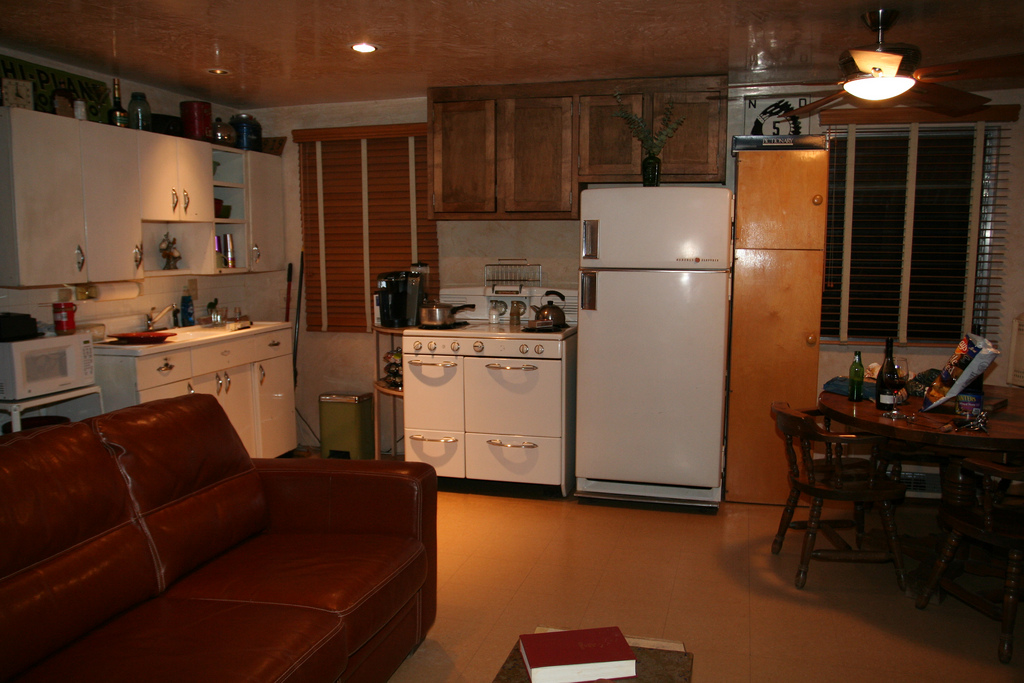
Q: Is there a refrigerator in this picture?
A: Yes, there is a refrigerator.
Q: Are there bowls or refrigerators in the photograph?
A: Yes, there is a refrigerator.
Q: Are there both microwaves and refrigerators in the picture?
A: Yes, there are both a refrigerator and a microwave.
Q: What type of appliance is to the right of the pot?
A: The appliance is a refrigerator.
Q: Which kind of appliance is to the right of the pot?
A: The appliance is a refrigerator.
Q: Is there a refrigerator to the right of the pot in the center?
A: Yes, there is a refrigerator to the right of the pot.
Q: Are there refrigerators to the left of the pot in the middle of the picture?
A: No, the refrigerator is to the right of the pot.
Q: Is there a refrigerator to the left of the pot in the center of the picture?
A: No, the refrigerator is to the right of the pot.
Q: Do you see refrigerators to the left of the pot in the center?
A: No, the refrigerator is to the right of the pot.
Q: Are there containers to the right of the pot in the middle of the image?
A: No, there is a refrigerator to the right of the pot.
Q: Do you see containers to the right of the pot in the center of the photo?
A: No, there is a refrigerator to the right of the pot.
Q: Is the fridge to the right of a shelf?
A: No, the fridge is to the right of the pot.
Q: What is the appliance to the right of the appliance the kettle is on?
A: The appliance is a refrigerator.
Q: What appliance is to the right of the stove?
A: The appliance is a refrigerator.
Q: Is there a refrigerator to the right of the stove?
A: Yes, there is a refrigerator to the right of the stove.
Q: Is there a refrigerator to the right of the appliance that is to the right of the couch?
A: Yes, there is a refrigerator to the right of the stove.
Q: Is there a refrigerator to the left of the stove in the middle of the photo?
A: No, the refrigerator is to the right of the stove.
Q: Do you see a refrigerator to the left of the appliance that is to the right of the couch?
A: No, the refrigerator is to the right of the stove.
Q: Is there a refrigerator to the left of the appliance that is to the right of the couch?
A: No, the refrigerator is to the right of the stove.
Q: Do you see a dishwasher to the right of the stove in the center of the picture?
A: No, there is a refrigerator to the right of the stove.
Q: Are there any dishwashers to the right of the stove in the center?
A: No, there is a refrigerator to the right of the stove.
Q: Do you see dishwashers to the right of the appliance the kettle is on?
A: No, there is a refrigerator to the right of the stove.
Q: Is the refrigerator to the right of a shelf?
A: No, the refrigerator is to the right of the stove.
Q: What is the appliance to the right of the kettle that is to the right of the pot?
A: The appliance is a refrigerator.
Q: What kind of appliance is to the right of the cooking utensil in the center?
A: The appliance is a refrigerator.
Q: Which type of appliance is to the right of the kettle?
A: The appliance is a refrigerator.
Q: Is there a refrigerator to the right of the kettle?
A: Yes, there is a refrigerator to the right of the kettle.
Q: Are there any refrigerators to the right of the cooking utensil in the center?
A: Yes, there is a refrigerator to the right of the kettle.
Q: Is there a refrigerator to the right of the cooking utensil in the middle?
A: Yes, there is a refrigerator to the right of the kettle.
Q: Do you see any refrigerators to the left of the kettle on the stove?
A: No, the refrigerator is to the right of the kettle.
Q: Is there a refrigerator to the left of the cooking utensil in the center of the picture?
A: No, the refrigerator is to the right of the kettle.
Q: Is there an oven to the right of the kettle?
A: No, there is a refrigerator to the right of the kettle.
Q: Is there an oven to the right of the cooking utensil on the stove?
A: No, there is a refrigerator to the right of the kettle.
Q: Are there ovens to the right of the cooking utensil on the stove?
A: No, there is a refrigerator to the right of the kettle.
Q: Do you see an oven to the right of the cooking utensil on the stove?
A: No, there is a refrigerator to the right of the kettle.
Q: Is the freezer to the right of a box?
A: No, the freezer is to the right of a kettle.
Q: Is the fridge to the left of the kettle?
A: No, the fridge is to the right of the kettle.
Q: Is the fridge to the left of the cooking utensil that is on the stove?
A: No, the fridge is to the right of the kettle.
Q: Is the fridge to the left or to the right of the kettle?
A: The fridge is to the right of the kettle.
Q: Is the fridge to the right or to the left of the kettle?
A: The fridge is to the right of the kettle.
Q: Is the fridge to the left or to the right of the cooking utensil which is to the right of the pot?
A: The fridge is to the right of the kettle.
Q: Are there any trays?
A: No, there are no trays.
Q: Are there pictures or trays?
A: No, there are no trays or pictures.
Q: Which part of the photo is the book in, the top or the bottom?
A: The book is in the bottom of the image.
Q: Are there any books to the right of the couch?
A: Yes, there is a book to the right of the couch.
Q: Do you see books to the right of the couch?
A: Yes, there is a book to the right of the couch.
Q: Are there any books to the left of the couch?
A: No, the book is to the right of the couch.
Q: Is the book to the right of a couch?
A: Yes, the book is to the right of a couch.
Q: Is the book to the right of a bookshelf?
A: No, the book is to the right of a couch.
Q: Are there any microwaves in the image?
A: Yes, there is a microwave.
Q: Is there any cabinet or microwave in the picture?
A: Yes, there is a microwave.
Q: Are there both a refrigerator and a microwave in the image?
A: Yes, there are both a microwave and a refrigerator.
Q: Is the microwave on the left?
A: Yes, the microwave is on the left of the image.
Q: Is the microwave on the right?
A: No, the microwave is on the left of the image.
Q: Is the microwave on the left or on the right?
A: The microwave is on the left of the image.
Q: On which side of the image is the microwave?
A: The microwave is on the left of the image.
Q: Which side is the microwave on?
A: The microwave is on the left of the image.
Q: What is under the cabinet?
A: The microwave is under the cabinet.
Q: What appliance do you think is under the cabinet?
A: The appliance is a microwave.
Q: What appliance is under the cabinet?
A: The appliance is a microwave.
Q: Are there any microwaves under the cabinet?
A: Yes, there is a microwave under the cabinet.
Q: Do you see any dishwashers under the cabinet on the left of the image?
A: No, there is a microwave under the cabinet.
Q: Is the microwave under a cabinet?
A: Yes, the microwave is under a cabinet.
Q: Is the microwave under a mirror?
A: No, the microwave is under a cabinet.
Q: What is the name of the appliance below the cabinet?
A: The appliance is a microwave.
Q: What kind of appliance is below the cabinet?
A: The appliance is a microwave.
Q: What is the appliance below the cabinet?
A: The appliance is a microwave.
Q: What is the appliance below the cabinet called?
A: The appliance is a microwave.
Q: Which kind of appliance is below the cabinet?
A: The appliance is a microwave.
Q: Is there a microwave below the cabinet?
A: Yes, there is a microwave below the cabinet.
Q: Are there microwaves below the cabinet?
A: Yes, there is a microwave below the cabinet.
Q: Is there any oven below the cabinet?
A: No, there is a microwave below the cabinet.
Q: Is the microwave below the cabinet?
A: Yes, the microwave is below the cabinet.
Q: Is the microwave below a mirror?
A: No, the microwave is below the cabinet.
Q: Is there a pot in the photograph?
A: Yes, there is a pot.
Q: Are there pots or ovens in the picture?
A: Yes, there is a pot.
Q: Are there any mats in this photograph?
A: No, there are no mats.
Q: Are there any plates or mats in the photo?
A: No, there are no mats or plates.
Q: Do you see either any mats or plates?
A: No, there are no mats or plates.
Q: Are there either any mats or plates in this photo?
A: No, there are no mats or plates.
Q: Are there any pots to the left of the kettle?
A: Yes, there is a pot to the left of the kettle.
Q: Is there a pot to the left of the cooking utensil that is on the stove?
A: Yes, there is a pot to the left of the kettle.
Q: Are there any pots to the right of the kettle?
A: No, the pot is to the left of the kettle.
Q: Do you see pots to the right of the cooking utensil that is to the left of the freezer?
A: No, the pot is to the left of the kettle.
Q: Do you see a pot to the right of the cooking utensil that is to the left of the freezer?
A: No, the pot is to the left of the kettle.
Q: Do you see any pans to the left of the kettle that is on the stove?
A: No, there is a pot to the left of the kettle.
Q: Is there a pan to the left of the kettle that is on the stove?
A: No, there is a pot to the left of the kettle.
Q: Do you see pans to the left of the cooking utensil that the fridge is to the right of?
A: No, there is a pot to the left of the kettle.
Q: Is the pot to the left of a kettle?
A: Yes, the pot is to the left of a kettle.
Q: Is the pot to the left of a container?
A: No, the pot is to the left of a kettle.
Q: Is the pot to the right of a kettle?
A: No, the pot is to the left of a kettle.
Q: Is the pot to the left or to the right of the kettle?
A: The pot is to the left of the kettle.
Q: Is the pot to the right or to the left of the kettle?
A: The pot is to the left of the kettle.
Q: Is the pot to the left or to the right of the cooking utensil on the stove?
A: The pot is to the left of the kettle.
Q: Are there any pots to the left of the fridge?
A: Yes, there is a pot to the left of the fridge.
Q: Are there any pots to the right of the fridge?
A: No, the pot is to the left of the fridge.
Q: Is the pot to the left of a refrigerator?
A: Yes, the pot is to the left of a refrigerator.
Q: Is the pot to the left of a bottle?
A: No, the pot is to the left of a refrigerator.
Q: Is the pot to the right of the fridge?
A: No, the pot is to the left of the fridge.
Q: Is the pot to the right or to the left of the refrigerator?
A: The pot is to the left of the refrigerator.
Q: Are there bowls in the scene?
A: No, there are no bowls.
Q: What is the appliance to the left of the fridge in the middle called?
A: The appliance is a stove.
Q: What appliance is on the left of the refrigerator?
A: The appliance is a stove.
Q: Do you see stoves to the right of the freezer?
A: No, the stove is to the left of the freezer.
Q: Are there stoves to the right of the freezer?
A: No, the stove is to the left of the freezer.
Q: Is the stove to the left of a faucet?
A: No, the stove is to the left of the refrigerator.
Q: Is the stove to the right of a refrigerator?
A: No, the stove is to the left of a refrigerator.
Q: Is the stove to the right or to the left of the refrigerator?
A: The stove is to the left of the refrigerator.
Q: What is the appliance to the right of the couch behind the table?
A: The appliance is a stove.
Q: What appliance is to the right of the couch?
A: The appliance is a stove.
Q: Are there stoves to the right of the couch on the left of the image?
A: Yes, there is a stove to the right of the couch.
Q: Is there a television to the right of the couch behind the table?
A: No, there is a stove to the right of the couch.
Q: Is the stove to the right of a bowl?
A: No, the stove is to the right of the couch.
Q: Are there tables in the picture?
A: Yes, there is a table.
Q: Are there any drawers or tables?
A: Yes, there is a table.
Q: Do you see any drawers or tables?
A: Yes, there is a table.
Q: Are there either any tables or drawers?
A: Yes, there is a table.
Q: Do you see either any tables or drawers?
A: Yes, there is a table.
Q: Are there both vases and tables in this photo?
A: Yes, there are both a table and a vase.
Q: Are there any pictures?
A: No, there are no pictures.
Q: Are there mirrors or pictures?
A: No, there are no pictures or mirrors.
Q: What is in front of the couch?
A: The table is in front of the couch.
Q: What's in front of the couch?
A: The table is in front of the couch.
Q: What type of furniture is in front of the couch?
A: The piece of furniture is a table.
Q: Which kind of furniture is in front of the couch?
A: The piece of furniture is a table.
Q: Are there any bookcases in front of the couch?
A: No, there is a table in front of the couch.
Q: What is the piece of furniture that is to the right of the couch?
A: The piece of furniture is a table.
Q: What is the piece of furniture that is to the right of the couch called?
A: The piece of furniture is a table.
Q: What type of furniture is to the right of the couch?
A: The piece of furniture is a table.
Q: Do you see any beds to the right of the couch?
A: No, there is a table to the right of the couch.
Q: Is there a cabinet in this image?
A: Yes, there is a cabinet.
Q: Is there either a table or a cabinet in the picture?
A: Yes, there is a cabinet.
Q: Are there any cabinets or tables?
A: Yes, there is a cabinet.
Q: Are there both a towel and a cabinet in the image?
A: No, there is a cabinet but no towels.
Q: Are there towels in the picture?
A: No, there are no towels.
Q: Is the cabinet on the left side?
A: Yes, the cabinet is on the left of the image.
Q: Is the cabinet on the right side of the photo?
A: No, the cabinet is on the left of the image.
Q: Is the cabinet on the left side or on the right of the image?
A: The cabinet is on the left of the image.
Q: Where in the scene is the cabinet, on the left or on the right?
A: The cabinet is on the left of the image.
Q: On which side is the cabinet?
A: The cabinet is on the left of the image.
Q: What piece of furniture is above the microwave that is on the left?
A: The piece of furniture is a cabinet.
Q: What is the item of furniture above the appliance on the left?
A: The piece of furniture is a cabinet.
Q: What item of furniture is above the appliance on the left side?
A: The piece of furniture is a cabinet.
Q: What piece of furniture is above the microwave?
A: The piece of furniture is a cabinet.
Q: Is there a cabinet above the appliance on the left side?
A: Yes, there is a cabinet above the microwave.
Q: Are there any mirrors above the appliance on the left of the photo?
A: No, there is a cabinet above the microwave.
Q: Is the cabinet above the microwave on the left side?
A: Yes, the cabinet is above the microwave.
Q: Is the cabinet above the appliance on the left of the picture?
A: Yes, the cabinet is above the microwave.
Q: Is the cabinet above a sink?
A: No, the cabinet is above the microwave.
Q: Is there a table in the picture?
A: Yes, there is a table.